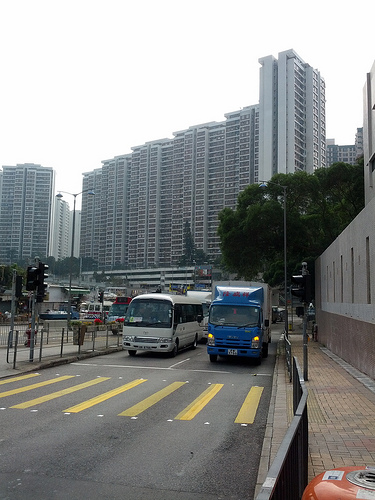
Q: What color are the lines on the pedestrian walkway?
A: Yellow.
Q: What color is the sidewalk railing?
A: Black.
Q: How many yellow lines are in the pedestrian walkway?
A: 7.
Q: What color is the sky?
A: White.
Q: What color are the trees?
A: Green.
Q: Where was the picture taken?
A: In a city.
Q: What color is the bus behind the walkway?
A: White.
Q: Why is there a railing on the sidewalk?
A: To keep pedestrians safe.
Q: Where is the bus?
A: On the road.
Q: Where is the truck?
A: To the right of the bus.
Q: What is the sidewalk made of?
A: Brick.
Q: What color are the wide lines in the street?
A: Yellow.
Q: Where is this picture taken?
A: The street.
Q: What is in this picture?
A: A cityscape.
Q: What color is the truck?
A: Blue.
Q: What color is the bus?
A: White.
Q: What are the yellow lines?
A: A crosswalk.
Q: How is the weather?
A: Overcast.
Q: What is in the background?
A: A building.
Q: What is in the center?
A: A road.